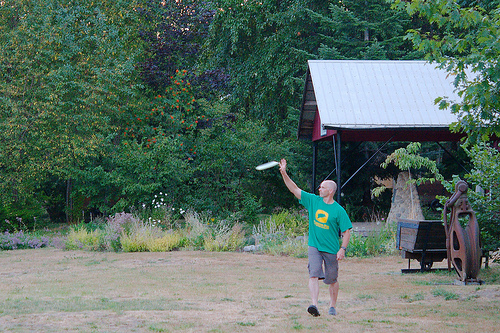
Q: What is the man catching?
A: Frisbee.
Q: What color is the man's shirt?
A: Green.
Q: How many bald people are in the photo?
A: One.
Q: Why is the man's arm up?
A: Frisbee.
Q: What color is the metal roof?
A: White.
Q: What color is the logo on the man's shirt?
A: Yellow.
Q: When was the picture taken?
A: Daytime.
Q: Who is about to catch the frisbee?
A: Man.